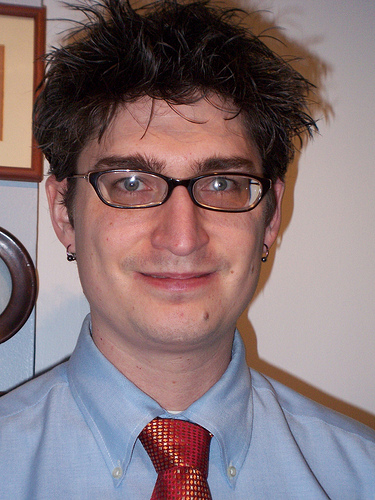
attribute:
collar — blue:
[66, 312, 254, 490]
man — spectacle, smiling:
[1, 1, 374, 499]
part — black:
[259, 243, 270, 264]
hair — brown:
[32, 1, 320, 178]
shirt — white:
[167, 410, 185, 413]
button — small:
[112, 467, 124, 481]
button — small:
[227, 464, 237, 478]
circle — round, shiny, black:
[1, 227, 37, 343]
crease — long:
[260, 375, 328, 499]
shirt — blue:
[0, 313, 374, 499]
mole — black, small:
[201, 312, 209, 322]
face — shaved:
[71, 94, 264, 348]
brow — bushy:
[92, 152, 165, 173]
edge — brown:
[31, 6, 47, 182]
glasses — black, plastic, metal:
[65, 166, 273, 214]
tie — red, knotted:
[138, 419, 211, 500]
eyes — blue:
[112, 175, 237, 193]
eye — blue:
[114, 177, 151, 193]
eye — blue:
[202, 175, 239, 189]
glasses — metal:
[68, 171, 90, 183]